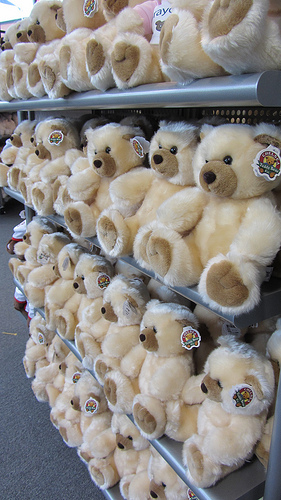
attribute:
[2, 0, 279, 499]
bears — stuffed, for sale, in the store, cream colored, in a row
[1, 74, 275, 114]
shelf — silver, grey silver, grey metal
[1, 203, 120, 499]
floor — carpeted, grey carpeted, grey carpeting, grey carpet, grey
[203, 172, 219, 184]
nose — black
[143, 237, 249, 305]
feet — brown, tan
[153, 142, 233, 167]
eyes — black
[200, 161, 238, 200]
muzzle — tan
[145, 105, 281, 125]
shelf backing — metal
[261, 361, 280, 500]
end post — metal